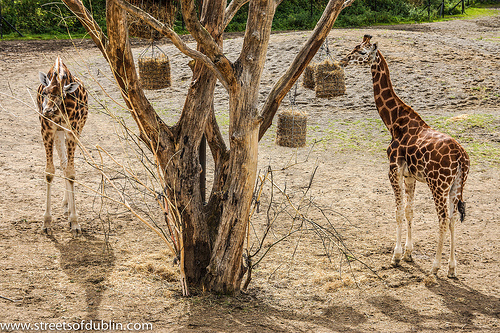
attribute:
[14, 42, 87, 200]
giraffe — eating, brown, white, bending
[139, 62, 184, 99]
hay — hanging, brown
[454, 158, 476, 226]
tail — black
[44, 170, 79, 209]
legs — four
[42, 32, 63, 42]
grass — green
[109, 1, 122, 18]
wood — brown